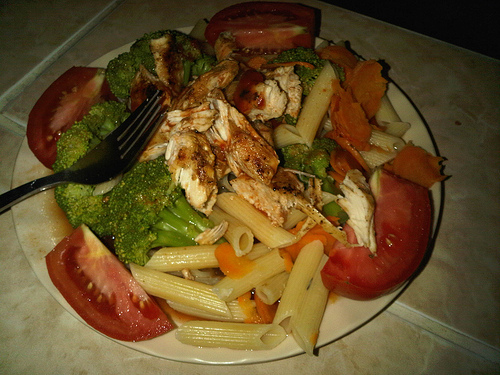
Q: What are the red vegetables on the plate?
A: Tomatoes.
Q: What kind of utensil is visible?
A: Fork.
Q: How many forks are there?
A: One.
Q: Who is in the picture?
A: No one.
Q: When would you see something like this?
A: Meal time.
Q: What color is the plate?
A: White.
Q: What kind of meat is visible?
A: Chicken.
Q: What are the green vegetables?
A: Broccoli.